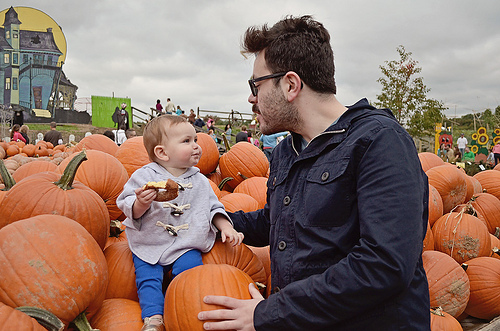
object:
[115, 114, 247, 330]
infant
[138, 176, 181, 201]
donut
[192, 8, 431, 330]
man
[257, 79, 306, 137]
whiskers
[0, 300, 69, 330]
pumpkin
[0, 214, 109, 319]
pile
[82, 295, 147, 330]
pumpkin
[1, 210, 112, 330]
pumpkin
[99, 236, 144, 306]
pumpkin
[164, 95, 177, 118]
man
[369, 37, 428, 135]
tree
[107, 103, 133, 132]
decoration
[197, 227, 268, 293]
pumpkin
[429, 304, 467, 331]
pumpkin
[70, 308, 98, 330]
stem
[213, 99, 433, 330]
jacket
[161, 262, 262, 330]
pumpkin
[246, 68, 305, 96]
glasses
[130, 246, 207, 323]
pants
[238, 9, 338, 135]
head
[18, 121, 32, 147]
woman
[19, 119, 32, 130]
head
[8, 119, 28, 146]
woman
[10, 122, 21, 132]
head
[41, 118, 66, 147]
man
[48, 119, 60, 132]
head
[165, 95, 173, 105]
head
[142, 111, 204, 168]
head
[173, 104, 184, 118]
woman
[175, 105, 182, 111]
head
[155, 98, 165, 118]
woman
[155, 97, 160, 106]
head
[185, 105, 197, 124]
woman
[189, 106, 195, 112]
head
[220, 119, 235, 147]
woman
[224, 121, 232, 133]
head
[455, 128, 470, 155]
man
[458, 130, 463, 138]
head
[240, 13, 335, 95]
hair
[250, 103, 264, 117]
moustache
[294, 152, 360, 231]
pocket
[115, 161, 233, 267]
jacket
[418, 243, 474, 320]
pumpkin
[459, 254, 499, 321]
pumpkin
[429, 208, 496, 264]
pumpkin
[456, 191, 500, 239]
pumpkin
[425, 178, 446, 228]
pumpkin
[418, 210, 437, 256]
pumpkin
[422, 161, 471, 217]
pumpkin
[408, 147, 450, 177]
pumpkin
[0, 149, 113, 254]
pumpkin